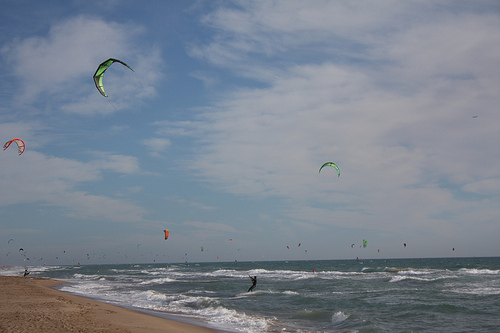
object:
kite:
[93, 58, 136, 98]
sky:
[0, 0, 500, 259]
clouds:
[0, 0, 500, 232]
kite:
[2, 138, 25, 156]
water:
[0, 255, 500, 333]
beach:
[0, 275, 217, 333]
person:
[247, 275, 257, 292]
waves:
[61, 276, 273, 333]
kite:
[319, 162, 340, 178]